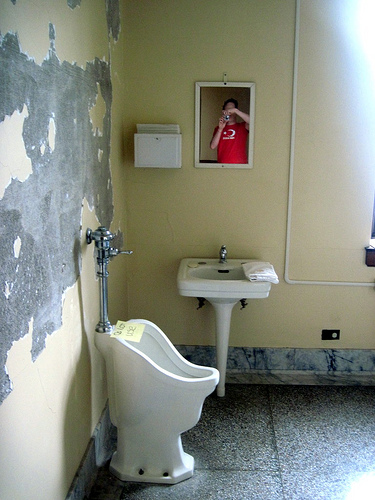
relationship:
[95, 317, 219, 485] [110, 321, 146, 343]
urinal has sign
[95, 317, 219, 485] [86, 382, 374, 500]
urinal connected to floor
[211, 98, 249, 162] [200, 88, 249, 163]
reflection in mirror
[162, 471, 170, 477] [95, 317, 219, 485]
bolt holding urinal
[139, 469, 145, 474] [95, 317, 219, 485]
bolt holding urinal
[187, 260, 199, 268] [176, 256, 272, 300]
soap bar on sink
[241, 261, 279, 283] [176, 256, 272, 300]
towel resting on sink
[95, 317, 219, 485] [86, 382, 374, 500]
urinal on floor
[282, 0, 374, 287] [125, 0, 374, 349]
water pipe on wall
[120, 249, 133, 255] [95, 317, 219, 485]
handle on urinal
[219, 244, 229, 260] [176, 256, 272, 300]
faucet on sink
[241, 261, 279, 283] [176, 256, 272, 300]
towel on side of sink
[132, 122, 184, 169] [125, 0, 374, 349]
paper towel holder on wall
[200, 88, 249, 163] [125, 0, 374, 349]
mirror on wall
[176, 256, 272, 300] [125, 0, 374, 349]
sink against wall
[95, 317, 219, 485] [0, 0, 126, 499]
urinal against wall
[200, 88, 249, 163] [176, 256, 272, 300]
mirror above sink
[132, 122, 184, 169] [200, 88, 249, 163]
paper towel holder next to mirror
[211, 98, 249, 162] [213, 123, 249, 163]
reflection wearing shirt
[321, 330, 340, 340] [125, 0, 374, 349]
outlet on wall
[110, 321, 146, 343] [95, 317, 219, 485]
sign on urinal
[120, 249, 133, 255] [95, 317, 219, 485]
handle attached to urinal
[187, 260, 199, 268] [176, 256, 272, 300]
soap bar resting on sink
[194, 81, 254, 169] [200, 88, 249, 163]
frame on mirror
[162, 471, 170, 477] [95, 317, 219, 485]
bolt on side of urinal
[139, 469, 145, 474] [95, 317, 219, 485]
bolt on side of urinal